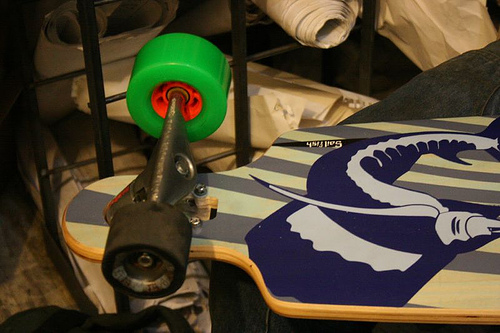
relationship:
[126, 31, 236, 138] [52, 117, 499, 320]
wheels in board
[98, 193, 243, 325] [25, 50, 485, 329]
wheel in skateboard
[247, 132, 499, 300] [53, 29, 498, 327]
picture in skateboard